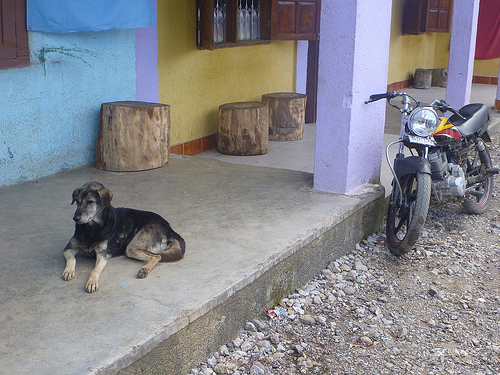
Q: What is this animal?
A: A dog.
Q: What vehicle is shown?
A: A motorbike.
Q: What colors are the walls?
A: Blue and yellow.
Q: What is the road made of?
A: Gravel and rock.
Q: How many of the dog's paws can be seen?
A: Three.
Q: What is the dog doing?
A: Lying down.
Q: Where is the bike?
A: Parking near the curb.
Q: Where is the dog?
A: On the sidewalk.